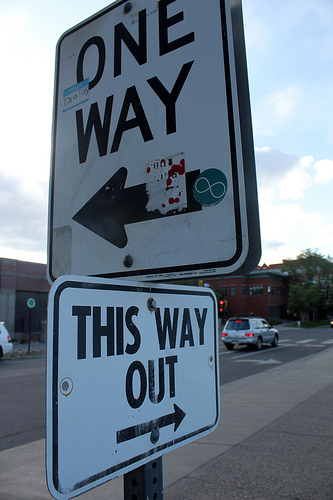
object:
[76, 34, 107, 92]
letters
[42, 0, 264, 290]
sign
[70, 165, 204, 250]
arrow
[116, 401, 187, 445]
arrow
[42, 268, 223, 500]
sign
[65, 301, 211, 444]
exit here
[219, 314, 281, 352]
car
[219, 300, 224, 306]
light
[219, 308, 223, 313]
traffic signal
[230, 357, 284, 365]
markings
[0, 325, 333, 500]
street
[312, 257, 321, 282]
trees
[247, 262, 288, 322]
buidling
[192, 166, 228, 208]
sticker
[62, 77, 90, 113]
sticker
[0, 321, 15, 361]
van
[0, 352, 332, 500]
sidewalk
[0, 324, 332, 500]
road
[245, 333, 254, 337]
taillights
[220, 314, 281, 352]
van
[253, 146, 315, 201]
clouds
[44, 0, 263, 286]
street sign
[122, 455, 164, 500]
pole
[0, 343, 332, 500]
surface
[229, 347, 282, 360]
lines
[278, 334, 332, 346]
crosswalk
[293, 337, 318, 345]
stripes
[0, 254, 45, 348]
wall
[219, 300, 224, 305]
stoplight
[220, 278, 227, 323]
post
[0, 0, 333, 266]
skies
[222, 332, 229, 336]
break lights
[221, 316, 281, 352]
truck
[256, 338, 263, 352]
wheel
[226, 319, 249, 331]
rear window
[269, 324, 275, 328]
side mirror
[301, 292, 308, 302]
leaves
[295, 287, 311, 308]
tree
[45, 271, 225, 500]
sign post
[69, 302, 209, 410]
"this way out"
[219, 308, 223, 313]
lights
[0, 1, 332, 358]
background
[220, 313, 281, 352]
station wagon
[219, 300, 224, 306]
traffic light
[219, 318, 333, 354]
intersection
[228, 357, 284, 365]
arrow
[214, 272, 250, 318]
building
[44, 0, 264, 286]
top sign